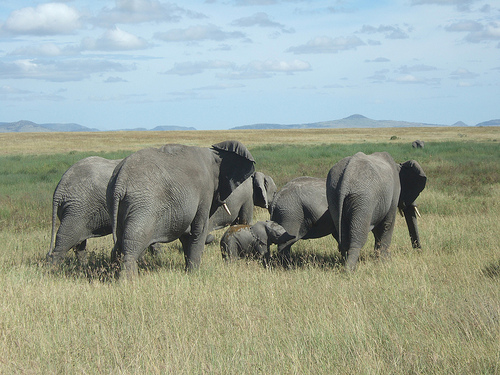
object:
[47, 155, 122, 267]
elephant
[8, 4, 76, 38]
cloud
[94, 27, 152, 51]
cloud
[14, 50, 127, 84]
cloud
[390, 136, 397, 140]
elephant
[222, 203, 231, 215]
tusks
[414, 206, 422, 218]
tusks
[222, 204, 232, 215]
tusks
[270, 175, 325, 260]
elephants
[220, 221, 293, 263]
elephant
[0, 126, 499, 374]
plain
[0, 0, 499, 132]
sky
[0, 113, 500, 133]
mountains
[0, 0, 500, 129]
distance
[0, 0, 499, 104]
clouds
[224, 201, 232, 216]
tusk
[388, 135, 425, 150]
two elephants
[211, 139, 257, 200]
ear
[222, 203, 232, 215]
elephant tusks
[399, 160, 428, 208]
ears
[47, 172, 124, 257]
tails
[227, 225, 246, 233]
brown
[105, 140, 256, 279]
elephant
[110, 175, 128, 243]
tail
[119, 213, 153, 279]
back leg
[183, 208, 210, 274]
front leg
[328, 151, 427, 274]
elephant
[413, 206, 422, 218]
trunk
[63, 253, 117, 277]
shadows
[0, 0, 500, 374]
daylight